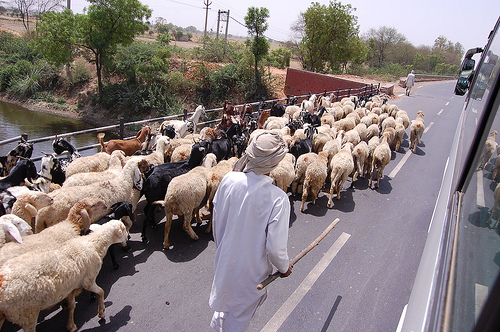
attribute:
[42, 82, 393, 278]
sheep — light-colored, in herd, in flock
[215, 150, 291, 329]
man — walking, tall, shepherd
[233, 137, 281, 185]
turban — beige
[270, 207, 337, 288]
stick — brown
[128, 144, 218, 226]
goat — black, brown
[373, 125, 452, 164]
line — painted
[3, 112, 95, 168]
water — calm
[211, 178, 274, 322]
dress — white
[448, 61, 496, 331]
bus — large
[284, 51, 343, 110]
wall — brick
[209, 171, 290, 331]
clothing — white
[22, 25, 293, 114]
bushes — green